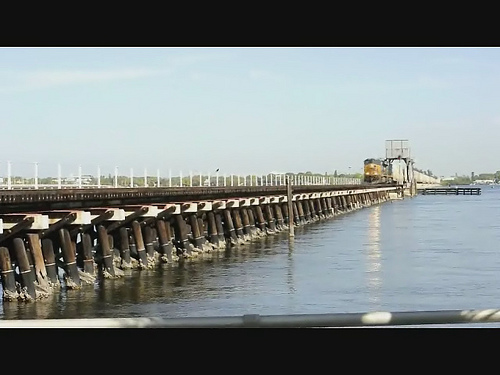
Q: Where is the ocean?
A: Under the dock.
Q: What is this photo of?
A: A dock on the water.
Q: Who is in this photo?
A: No One.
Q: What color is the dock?
A: Brown and white.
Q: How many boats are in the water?
A: None.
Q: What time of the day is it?
A: Mid afternoon.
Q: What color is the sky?
A: Blue.